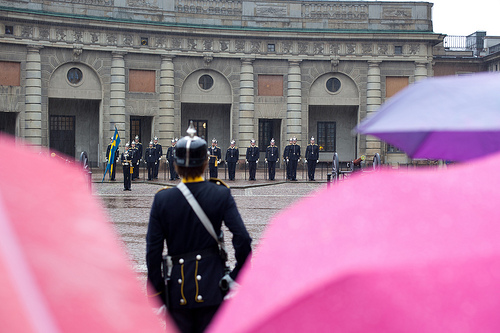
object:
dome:
[186, 120, 197, 135]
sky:
[431, 0, 494, 49]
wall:
[401, 181, 500, 227]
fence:
[444, 30, 498, 51]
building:
[0, 0, 499, 155]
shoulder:
[192, 178, 235, 203]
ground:
[0, 71, 495, 329]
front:
[0, 2, 430, 168]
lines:
[89, 182, 312, 195]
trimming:
[0, 0, 445, 43]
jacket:
[145, 178, 253, 307]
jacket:
[305, 143, 320, 159]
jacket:
[265, 145, 278, 161]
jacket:
[208, 146, 221, 163]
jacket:
[246, 145, 260, 161]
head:
[173, 135, 208, 179]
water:
[99, 194, 150, 208]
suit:
[146, 177, 253, 328]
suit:
[305, 143, 319, 180]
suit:
[264, 145, 279, 181]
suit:
[225, 146, 239, 181]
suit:
[144, 147, 157, 181]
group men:
[106, 134, 322, 189]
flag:
[100, 125, 120, 182]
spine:
[367, 70, 426, 157]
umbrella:
[353, 70, 500, 162]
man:
[304, 138, 319, 180]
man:
[283, 137, 301, 181]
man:
[263, 139, 278, 181]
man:
[245, 140, 259, 181]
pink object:
[204, 148, 499, 332]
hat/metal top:
[186, 120, 197, 136]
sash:
[176, 182, 218, 243]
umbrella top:
[201, 151, 500, 332]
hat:
[173, 121, 208, 167]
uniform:
[144, 175, 251, 329]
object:
[300, 235, 410, 282]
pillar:
[25, 54, 431, 162]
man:
[145, 135, 251, 332]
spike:
[186, 120, 196, 136]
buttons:
[178, 255, 203, 303]